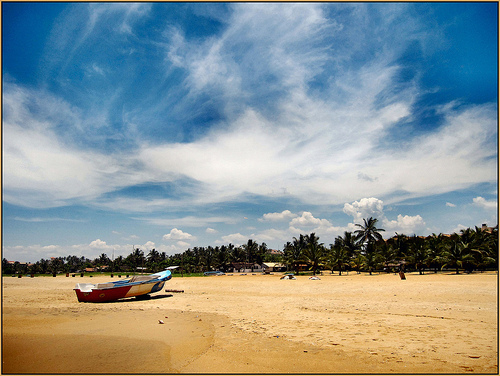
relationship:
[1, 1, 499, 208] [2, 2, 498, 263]
clouds in sky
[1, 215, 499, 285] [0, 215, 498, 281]
trees in row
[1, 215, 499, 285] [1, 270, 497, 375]
trees along beach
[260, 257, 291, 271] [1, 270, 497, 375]
house along beach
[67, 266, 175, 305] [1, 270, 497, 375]
boat on beach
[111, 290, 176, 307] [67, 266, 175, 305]
shadow near boat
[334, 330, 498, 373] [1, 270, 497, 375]
footprints in beach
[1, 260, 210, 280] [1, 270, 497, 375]
park near beach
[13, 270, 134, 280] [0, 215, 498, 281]
cylinders in row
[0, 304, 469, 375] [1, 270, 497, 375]
marks on beach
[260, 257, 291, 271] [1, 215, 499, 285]
house in trees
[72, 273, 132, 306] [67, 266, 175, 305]
back on boat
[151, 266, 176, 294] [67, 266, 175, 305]
front on boat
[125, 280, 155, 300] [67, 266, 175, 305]
stripe on boat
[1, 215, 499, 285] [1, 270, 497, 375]
trees behind beach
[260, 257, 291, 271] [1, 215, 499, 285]
house behind trees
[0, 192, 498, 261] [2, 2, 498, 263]
clouds in sky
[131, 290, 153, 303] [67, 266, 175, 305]
stone under boat